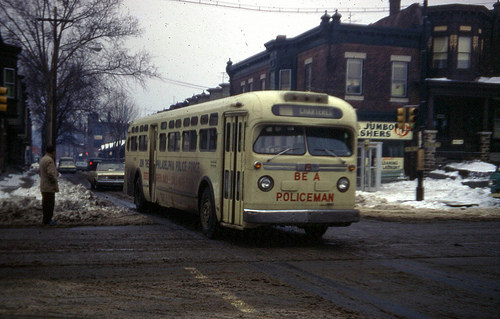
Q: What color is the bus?
A: Yellow.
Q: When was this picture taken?
A: Winter.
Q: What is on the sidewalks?
A: Snow.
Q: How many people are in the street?
A: One.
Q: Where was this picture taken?
A: City.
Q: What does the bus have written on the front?
A: Be a policeman.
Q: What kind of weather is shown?
A: Snowy.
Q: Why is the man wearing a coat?
A: It is cold.